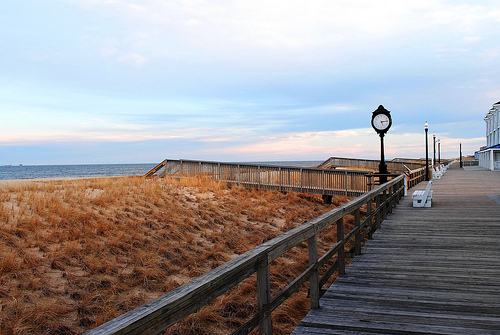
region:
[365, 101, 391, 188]
clock tower on pier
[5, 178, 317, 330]
dried grass on sand dune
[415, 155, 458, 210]
white benches on pier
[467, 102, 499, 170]
white building on pier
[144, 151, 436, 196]
stairways on the pier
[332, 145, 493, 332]
wooden slats of boardwalk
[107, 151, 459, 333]
railings along the boardwalk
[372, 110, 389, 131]
clock face on clock tower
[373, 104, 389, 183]
black tower surrounding clock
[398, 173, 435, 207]
first bench on boardwalk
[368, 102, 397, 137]
the frame of the clock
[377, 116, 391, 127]
the hands of a clock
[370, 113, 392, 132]
the face of a clock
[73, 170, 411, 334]
a brown wooden railing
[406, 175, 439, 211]
a white wooden bench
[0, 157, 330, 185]
blue ocean water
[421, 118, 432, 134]
a street light on the post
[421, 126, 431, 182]
a metal lamp post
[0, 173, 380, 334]
a yellow grassy field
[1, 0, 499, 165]
a cloudy blue sky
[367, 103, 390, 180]
Tall, metal clock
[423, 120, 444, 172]
Three lights along the boardwalk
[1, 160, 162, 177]
Blue ocean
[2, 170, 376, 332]
Scrub brush on a sandy beach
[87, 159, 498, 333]
Brown, wooden boardwalk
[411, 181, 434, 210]
White bench facing the ocean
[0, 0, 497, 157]
Cloudy, pink and blue sky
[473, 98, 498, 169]
Three story white building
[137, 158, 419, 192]
Two boardwalk passages to the beach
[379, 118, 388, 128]
Hands on a clock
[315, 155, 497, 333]
wood surface of boardwalk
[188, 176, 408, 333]
wood boards of railing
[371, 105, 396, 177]
clock on black pole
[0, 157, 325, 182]
water surface in distance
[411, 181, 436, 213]
white bench on boardwalk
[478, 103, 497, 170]
front of white building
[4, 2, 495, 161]
cloud cover in sky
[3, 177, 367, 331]
patches of brown grass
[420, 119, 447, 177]
line of lights on pole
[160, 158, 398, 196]
ramp leading to beach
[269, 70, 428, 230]
a clock that is outside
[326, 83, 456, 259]
a clock on a beach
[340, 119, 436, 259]
a clock in front of the sidewalk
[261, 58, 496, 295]
a clock on the corner of a sidewalk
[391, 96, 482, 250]
benches on a sidewalk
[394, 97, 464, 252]
white benches on a sidewalk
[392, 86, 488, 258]
a sidewalk with benches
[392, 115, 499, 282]
a sidewalk with white benches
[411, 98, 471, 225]
street lights on a sidewalk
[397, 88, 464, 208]
a sidewalk with lights